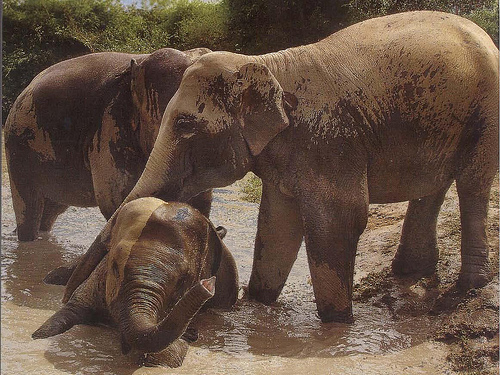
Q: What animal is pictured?
A: Elephant.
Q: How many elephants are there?
A: Three.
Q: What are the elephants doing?
A: Bathing.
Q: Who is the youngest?
A: Baby.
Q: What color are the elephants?
A: Grey.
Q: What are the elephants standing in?
A: Water.